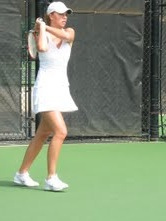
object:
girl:
[13, 0, 80, 193]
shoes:
[43, 176, 69, 192]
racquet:
[27, 17, 43, 60]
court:
[0, 142, 165, 221]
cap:
[46, 1, 74, 16]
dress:
[30, 29, 80, 115]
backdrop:
[79, 0, 143, 136]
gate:
[1, 0, 33, 142]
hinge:
[28, 116, 36, 124]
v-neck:
[48, 30, 65, 53]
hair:
[45, 13, 52, 25]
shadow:
[0, 180, 31, 189]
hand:
[35, 17, 47, 28]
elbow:
[37, 42, 50, 54]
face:
[55, 14, 69, 28]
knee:
[54, 127, 69, 140]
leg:
[17, 112, 51, 175]